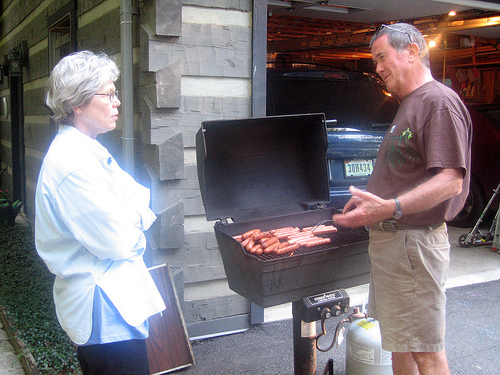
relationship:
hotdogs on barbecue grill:
[232, 190, 353, 332] [249, 245, 358, 301]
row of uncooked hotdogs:
[269, 186, 305, 279] [241, 201, 282, 259]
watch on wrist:
[382, 200, 401, 243] [381, 186, 408, 264]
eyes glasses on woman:
[99, 104, 122, 155] [75, 70, 135, 350]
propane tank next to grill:
[332, 336, 387, 375] [238, 284, 294, 349]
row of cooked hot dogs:
[269, 186, 305, 279] [243, 197, 295, 310]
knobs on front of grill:
[309, 291, 344, 347] [264, 280, 360, 333]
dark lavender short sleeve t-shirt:
[393, 144, 470, 244] [375, 134, 494, 176]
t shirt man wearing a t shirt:
[360, 82, 472, 233] [377, 128, 452, 182]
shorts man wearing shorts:
[369, 228, 450, 349] [367, 249, 428, 356]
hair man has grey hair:
[365, 21, 432, 70] [394, 50, 409, 71]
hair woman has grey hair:
[38, 50, 114, 121] [58, 50, 94, 105]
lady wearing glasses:
[32, 47, 167, 375] [89, 85, 143, 110]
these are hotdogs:
[260, 259, 327, 303] [232, 207, 364, 287]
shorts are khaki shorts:
[369, 228, 450, 349] [396, 267, 446, 344]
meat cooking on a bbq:
[258, 213, 336, 239] [233, 255, 321, 326]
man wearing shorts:
[328, 21, 475, 371] [364, 223, 452, 353]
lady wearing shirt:
[32, 47, 167, 375] [32, 120, 167, 347]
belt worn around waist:
[366, 219, 445, 231] [363, 209, 453, 233]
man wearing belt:
[328, 21, 475, 371] [366, 219, 445, 231]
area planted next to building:
[1, 220, 82, 372] [1, 0, 484, 343]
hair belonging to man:
[365, 21, 432, 70] [328, 21, 475, 371]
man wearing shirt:
[328, 21, 475, 371] [365, 76, 475, 227]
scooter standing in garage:
[455, 180, 484, 246] [2, 2, 484, 343]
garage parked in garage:
[239, 2, 484, 317] [2, 2, 484, 343]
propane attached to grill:
[343, 314, 392, 375] [194, 109, 371, 373]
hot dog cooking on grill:
[303, 235, 330, 246] [194, 109, 371, 373]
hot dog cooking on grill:
[275, 240, 301, 253] [194, 109, 371, 373]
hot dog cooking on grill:
[250, 229, 276, 241] [194, 109, 371, 373]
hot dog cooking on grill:
[238, 226, 261, 239] [194, 109, 371, 373]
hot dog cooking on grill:
[312, 226, 339, 234] [194, 109, 371, 373]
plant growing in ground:
[2, 222, 82, 372] [2, 212, 484, 372]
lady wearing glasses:
[32, 47, 168, 372] [92, 87, 121, 100]